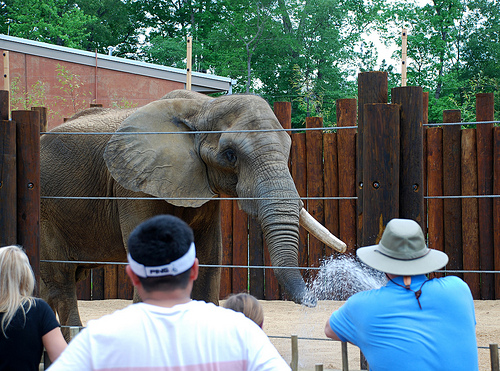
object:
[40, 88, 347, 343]
elephant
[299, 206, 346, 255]
tusk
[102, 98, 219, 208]
ear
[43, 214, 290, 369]
man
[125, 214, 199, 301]
head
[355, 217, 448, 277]
hat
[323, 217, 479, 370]
man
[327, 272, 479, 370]
t-shirt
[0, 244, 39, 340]
hair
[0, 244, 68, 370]
woman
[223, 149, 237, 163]
eye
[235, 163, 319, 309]
trunk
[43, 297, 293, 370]
shirt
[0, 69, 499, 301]
fence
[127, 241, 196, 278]
head band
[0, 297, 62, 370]
t-shirt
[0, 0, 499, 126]
trees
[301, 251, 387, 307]
water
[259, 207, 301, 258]
ridges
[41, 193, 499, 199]
wire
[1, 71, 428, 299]
posts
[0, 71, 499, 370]
pen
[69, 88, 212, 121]
hump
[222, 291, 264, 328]
hair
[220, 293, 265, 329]
kid